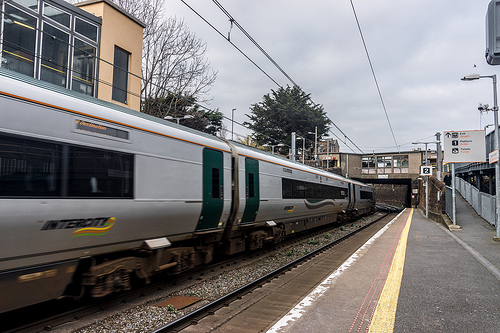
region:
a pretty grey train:
[1, 56, 377, 314]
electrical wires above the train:
[171, 0, 359, 169]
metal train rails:
[0, 198, 400, 329]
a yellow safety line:
[355, 201, 416, 332]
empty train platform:
[254, 207, 494, 329]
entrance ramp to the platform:
[425, 163, 496, 232]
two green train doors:
[182, 140, 274, 232]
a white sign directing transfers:
[438, 126, 489, 163]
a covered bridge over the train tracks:
[322, 147, 452, 184]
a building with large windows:
[9, 1, 153, 123]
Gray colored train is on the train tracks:
[3, 88, 396, 305]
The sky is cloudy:
[174, 6, 487, 151]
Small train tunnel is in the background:
[366, 171, 417, 216]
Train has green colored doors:
[193, 144, 273, 234]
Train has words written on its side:
[30, 208, 128, 256]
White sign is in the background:
[434, 125, 487, 172]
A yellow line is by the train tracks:
[356, 204, 423, 331]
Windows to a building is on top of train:
[7, 6, 117, 91]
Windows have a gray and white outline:
[8, 3, 103, 95]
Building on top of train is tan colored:
[97, 7, 158, 105]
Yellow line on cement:
[381, 231, 441, 318]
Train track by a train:
[248, 258, 324, 331]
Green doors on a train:
[181, 135, 262, 236]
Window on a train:
[33, 121, 162, 223]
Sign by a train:
[408, 144, 460, 236]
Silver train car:
[223, 133, 357, 274]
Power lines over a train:
[210, 34, 395, 239]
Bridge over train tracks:
[330, 145, 445, 205]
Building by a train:
[29, 17, 174, 87]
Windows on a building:
[9, 15, 125, 95]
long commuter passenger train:
[1, 67, 378, 305]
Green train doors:
[189, 145, 273, 239]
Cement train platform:
[291, 206, 466, 331]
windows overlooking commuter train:
[4, 2, 140, 94]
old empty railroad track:
[146, 205, 393, 330]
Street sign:
[426, 119, 496, 169]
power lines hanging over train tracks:
[164, 4, 417, 152]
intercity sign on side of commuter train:
[33, 208, 130, 239]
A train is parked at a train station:
[4, 68, 455, 330]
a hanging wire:
[298, 0, 408, 147]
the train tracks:
[121, 222, 347, 294]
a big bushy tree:
[238, 72, 333, 152]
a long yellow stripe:
[366, 202, 422, 329]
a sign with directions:
[438, 125, 493, 162]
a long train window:
[275, 172, 352, 207]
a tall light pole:
[455, 65, 497, 125]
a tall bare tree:
[130, 0, 210, 103]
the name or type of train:
[33, 210, 130, 245]